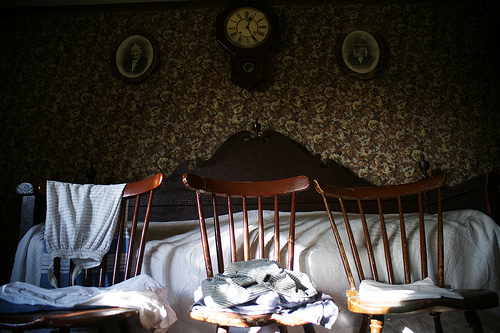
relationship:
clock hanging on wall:
[216, 7, 279, 52] [0, 1, 499, 183]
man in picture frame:
[350, 37, 372, 66] [334, 23, 388, 82]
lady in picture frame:
[126, 43, 143, 67] [111, 29, 158, 83]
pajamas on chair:
[40, 176, 120, 269] [12, 175, 165, 329]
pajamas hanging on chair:
[40, 176, 120, 269] [12, 175, 165, 329]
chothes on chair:
[193, 262, 313, 311] [182, 175, 325, 330]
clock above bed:
[216, 7, 279, 52] [24, 223, 499, 264]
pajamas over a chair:
[40, 176, 120, 269] [12, 175, 165, 329]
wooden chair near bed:
[310, 178, 499, 332] [24, 223, 499, 264]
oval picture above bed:
[111, 29, 158, 83] [24, 223, 499, 264]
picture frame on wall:
[334, 23, 388, 82] [0, 1, 499, 183]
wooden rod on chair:
[212, 198, 226, 273] [182, 175, 325, 330]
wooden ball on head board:
[251, 120, 263, 131] [101, 126, 409, 210]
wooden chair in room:
[312, 179, 497, 327] [2, 3, 492, 329]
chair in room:
[312, 179, 497, 327] [2, 3, 492, 329]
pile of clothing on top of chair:
[205, 263, 332, 332] [182, 175, 325, 330]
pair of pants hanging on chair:
[40, 176, 120, 269] [12, 175, 165, 329]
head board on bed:
[101, 126, 409, 210] [24, 223, 499, 264]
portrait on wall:
[111, 29, 158, 83] [0, 1, 499, 183]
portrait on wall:
[334, 23, 388, 82] [0, 1, 499, 183]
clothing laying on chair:
[0, 273, 177, 332] [182, 175, 325, 330]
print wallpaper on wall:
[3, 12, 498, 184] [0, 1, 499, 183]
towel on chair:
[355, 277, 446, 299] [312, 179, 497, 327]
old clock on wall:
[218, 8, 283, 88] [0, 1, 499, 183]